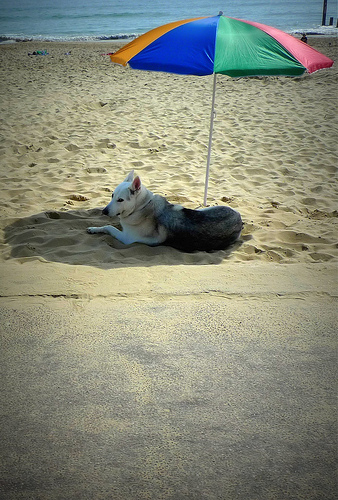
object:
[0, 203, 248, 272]
shadow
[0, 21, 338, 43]
waves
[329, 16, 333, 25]
stick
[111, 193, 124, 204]
eyes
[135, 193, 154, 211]
collar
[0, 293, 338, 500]
sand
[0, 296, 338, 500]
concrete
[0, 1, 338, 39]
water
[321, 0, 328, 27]
black post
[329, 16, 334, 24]
black post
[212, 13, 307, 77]
stripe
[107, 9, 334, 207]
umbrella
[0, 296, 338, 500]
pavement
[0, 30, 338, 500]
beach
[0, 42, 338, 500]
ground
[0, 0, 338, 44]
ocean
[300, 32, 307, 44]
person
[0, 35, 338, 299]
sands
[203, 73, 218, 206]
pole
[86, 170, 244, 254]
dog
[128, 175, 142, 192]
ear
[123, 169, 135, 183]
ear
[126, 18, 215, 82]
stripe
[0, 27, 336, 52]
shore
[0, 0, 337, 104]
background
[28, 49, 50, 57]
object